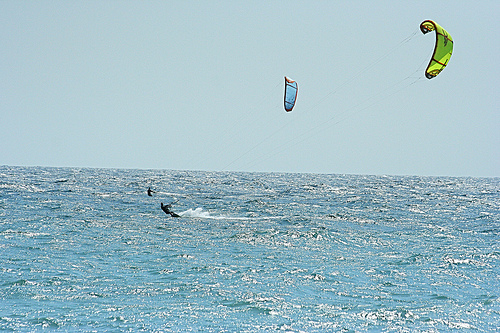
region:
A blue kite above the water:
[275, 74, 297, 121]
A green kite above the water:
[414, 14, 466, 79]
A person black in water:
[148, 193, 180, 224]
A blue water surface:
[58, 258, 205, 308]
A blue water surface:
[232, 253, 336, 328]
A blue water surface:
[347, 227, 477, 331]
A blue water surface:
[14, 163, 121, 213]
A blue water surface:
[220, 165, 350, 202]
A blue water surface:
[385, 175, 495, 245]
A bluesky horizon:
[48, 85, 246, 160]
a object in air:
[254, 68, 328, 128]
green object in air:
[377, 13, 498, 94]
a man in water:
[161, 185, 196, 225]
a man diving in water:
[149, 195, 203, 232]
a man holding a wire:
[156, 191, 195, 234]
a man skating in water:
[142, 191, 202, 231]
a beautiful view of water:
[12, 145, 435, 327]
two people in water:
[63, 153, 217, 241]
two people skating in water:
[99, 157, 218, 244]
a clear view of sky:
[25, 25, 462, 170]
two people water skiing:
[131, 178, 226, 234]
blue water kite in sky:
[260, 60, 320, 118]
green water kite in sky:
[372, 20, 457, 85]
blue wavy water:
[305, 215, 370, 248]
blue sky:
[135, 60, 185, 100]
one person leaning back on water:
[145, 196, 187, 226]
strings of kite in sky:
[390, 21, 418, 88]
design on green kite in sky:
[436, 22, 448, 47]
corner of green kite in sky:
[420, 57, 445, 84]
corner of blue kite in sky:
[277, 93, 304, 113]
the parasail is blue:
[261, 65, 335, 127]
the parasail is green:
[415, 8, 493, 120]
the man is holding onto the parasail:
[143, 198, 204, 225]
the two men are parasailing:
[132, 153, 258, 260]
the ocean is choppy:
[96, 220, 396, 328]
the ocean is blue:
[131, 247, 327, 312]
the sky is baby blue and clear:
[97, 82, 223, 165]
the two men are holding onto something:
[120, 130, 333, 241]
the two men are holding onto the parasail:
[115, 5, 480, 240]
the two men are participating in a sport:
[100, 16, 495, 245]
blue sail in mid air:
[289, 70, 306, 117]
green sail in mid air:
[409, 25, 452, 84]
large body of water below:
[117, 285, 280, 332]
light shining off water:
[216, 301, 268, 326]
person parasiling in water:
[161, 195, 187, 225]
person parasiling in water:
[143, 179, 157, 202]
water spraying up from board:
[177, 200, 222, 230]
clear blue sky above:
[27, 47, 147, 112]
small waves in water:
[179, 265, 327, 319]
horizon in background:
[38, 145, 455, 195]